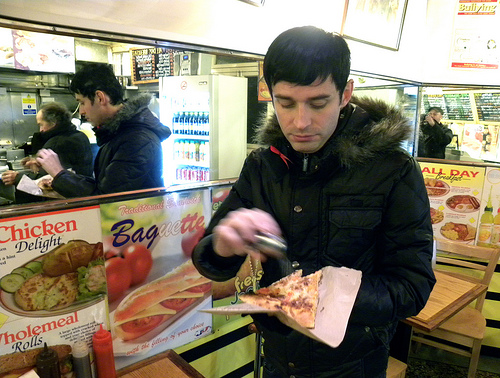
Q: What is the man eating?
A: Pizza.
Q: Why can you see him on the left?
A: A mirror.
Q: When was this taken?
A: Daytime.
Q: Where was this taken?
A: A restaurant.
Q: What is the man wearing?
A: A jacket.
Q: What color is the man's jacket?
A: Black.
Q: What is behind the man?
A: A table.